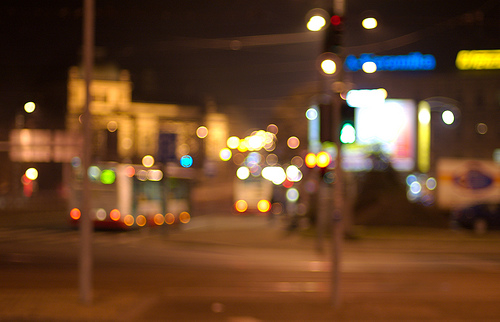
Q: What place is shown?
A: It is a road.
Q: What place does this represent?
A: It represents the road.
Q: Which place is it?
A: It is a road.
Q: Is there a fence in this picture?
A: No, there are no fences.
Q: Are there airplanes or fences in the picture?
A: No, there are no fences or airplanes.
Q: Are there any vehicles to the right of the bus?
A: Yes, there is a vehicle to the right of the bus.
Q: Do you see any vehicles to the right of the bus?
A: Yes, there is a vehicle to the right of the bus.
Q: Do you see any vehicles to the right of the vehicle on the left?
A: Yes, there is a vehicle to the right of the bus.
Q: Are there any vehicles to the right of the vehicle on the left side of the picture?
A: Yes, there is a vehicle to the right of the bus.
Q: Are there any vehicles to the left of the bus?
A: No, the vehicle is to the right of the bus.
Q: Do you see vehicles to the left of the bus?
A: No, the vehicle is to the right of the bus.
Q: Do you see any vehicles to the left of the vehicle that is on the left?
A: No, the vehicle is to the right of the bus.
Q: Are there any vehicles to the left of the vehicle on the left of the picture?
A: No, the vehicle is to the right of the bus.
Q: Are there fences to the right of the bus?
A: No, there is a vehicle to the right of the bus.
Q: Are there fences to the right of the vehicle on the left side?
A: No, there is a vehicle to the right of the bus.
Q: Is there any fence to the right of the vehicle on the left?
A: No, there is a vehicle to the right of the bus.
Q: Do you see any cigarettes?
A: No, there are no cigarettes.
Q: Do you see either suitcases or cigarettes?
A: No, there are no cigarettes or suitcases.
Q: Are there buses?
A: Yes, there is a bus.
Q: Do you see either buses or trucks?
A: Yes, there is a bus.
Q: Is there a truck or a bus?
A: Yes, there is a bus.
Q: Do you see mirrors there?
A: No, there are no mirrors.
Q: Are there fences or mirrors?
A: No, there are no mirrors or fences.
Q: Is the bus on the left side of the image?
A: Yes, the bus is on the left of the image.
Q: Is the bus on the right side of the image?
A: No, the bus is on the left of the image.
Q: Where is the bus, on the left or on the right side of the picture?
A: The bus is on the left of the image.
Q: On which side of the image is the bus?
A: The bus is on the left of the image.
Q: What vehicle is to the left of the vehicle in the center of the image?
A: The vehicle is a bus.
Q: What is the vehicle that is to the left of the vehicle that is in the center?
A: The vehicle is a bus.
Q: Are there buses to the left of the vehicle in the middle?
A: Yes, there is a bus to the left of the vehicle.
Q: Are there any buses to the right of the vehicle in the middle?
A: No, the bus is to the left of the vehicle.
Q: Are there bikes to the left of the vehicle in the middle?
A: No, there is a bus to the left of the vehicle.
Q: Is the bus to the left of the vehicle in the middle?
A: Yes, the bus is to the left of the vehicle.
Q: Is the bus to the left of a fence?
A: No, the bus is to the left of the vehicle.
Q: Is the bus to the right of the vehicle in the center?
A: No, the bus is to the left of the vehicle.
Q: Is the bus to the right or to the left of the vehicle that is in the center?
A: The bus is to the left of the vehicle.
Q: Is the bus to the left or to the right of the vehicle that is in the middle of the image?
A: The bus is to the left of the vehicle.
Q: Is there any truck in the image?
A: Yes, there is a truck.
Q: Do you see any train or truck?
A: Yes, there is a truck.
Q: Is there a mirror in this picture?
A: No, there are no mirrors.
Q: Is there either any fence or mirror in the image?
A: No, there are no mirrors or fences.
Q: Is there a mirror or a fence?
A: No, there are no mirrors or fences.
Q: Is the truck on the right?
A: Yes, the truck is on the right of the image.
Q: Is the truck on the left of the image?
A: No, the truck is on the right of the image.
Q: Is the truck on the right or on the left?
A: The truck is on the right of the image.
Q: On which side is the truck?
A: The truck is on the right of the image.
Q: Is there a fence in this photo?
A: No, there are no fences.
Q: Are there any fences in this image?
A: No, there are no fences.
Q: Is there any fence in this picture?
A: No, there are no fences.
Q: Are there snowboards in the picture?
A: No, there are no snowboards.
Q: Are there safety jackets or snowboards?
A: No, there are no snowboards or safety jackets.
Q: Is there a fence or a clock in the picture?
A: No, there are no fences or clocks.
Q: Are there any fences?
A: No, there are no fences.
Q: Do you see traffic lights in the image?
A: Yes, there is a traffic light.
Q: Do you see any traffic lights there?
A: Yes, there is a traffic light.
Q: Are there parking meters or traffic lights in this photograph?
A: Yes, there is a traffic light.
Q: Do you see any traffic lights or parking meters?
A: Yes, there is a traffic light.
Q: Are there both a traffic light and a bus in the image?
A: Yes, there are both a traffic light and a bus.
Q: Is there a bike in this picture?
A: No, there are no bikes.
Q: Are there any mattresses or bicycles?
A: No, there are no bicycles or mattresses.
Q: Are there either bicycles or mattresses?
A: No, there are no bicycles or mattresses.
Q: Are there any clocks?
A: No, there are no clocks.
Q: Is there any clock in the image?
A: No, there are no clocks.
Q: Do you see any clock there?
A: No, there are no clocks.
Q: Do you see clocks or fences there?
A: No, there are no clocks or fences.